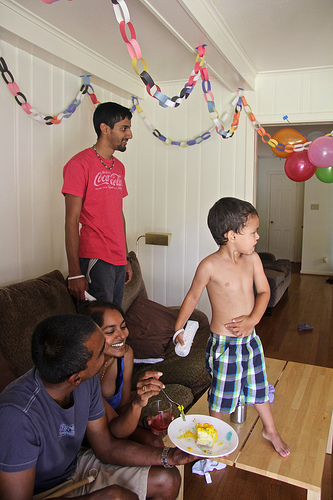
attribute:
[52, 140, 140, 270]
shirt — red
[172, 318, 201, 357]
controller — white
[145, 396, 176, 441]
glass — clear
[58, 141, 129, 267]
shirt — short sleeve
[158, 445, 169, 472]
wristwatch — silver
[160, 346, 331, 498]
table — light-colored, wooden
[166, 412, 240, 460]
plate — white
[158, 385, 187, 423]
fork — silver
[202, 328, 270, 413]
shorts — plaid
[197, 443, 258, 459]
plate — white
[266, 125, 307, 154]
balloon — orange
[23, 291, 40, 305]
couch — brown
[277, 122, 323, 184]
decoration — colored paper, chain-link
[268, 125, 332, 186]
balloons — group 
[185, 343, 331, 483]
table — folding, wooden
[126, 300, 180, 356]
pillow — decorative 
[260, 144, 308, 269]
door — white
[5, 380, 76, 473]
t-shirt — grey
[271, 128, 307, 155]
balloon — multi-colored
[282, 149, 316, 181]
balloon — multi-colored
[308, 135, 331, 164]
balloon — multi-colored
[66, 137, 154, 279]
shirt — red, short-sleeve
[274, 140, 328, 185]
balloon — red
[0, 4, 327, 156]
decorations — homemade, colorful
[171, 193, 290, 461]
boy — young, shirtless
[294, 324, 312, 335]
shoe — blue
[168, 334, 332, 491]
table — brown, coffee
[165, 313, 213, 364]
controller — white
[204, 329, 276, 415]
shorts — plaid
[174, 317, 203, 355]
controller — wii 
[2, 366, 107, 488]
shirt — blue